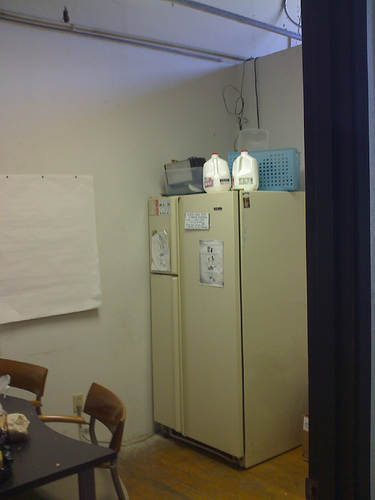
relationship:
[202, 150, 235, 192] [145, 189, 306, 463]
milk on top of refrigerator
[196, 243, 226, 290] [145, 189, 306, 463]
paper on top of refrigerator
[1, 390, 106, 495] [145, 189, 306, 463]
table in front of refrigerator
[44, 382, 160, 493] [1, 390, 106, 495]
chair at table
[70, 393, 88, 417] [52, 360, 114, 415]
outlet on top of wall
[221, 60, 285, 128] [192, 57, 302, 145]
cords over wall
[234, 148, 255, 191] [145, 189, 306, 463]
milk on top of refrigerator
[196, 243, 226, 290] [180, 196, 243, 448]
paper on top of door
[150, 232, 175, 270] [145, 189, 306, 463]
paper on top of refrigerator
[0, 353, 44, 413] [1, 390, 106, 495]
chair near table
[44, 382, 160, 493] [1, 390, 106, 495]
chair near table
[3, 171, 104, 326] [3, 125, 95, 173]
paper on top of wall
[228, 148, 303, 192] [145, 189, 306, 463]
basket on top of refrigerator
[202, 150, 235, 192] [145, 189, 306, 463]
milk on top of fridge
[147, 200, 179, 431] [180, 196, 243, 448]
freezer next to fridge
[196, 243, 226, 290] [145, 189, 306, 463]
paper on top of fridge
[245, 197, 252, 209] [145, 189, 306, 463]
magnet on side of fridge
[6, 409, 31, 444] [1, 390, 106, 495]
food on top of table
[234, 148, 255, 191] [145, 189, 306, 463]
container on top of refrigerator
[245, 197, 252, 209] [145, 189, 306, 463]
magnet on side fridge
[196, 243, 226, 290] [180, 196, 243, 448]
paper on front of door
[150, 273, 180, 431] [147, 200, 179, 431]
door on bottom